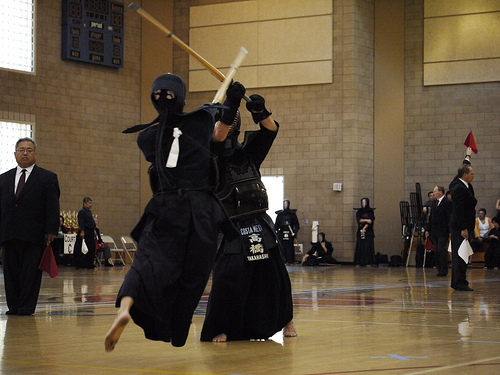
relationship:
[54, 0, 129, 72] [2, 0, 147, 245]
scoreboard on wall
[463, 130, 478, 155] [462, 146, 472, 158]
cloth in hand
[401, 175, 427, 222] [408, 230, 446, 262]
gates near bleachers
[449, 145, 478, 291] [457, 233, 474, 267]
man holding cloth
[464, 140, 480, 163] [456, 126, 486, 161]
hand holding cloth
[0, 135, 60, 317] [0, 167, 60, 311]
man wearing suit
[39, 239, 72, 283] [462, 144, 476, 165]
cloth in hand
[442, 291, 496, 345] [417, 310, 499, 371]
reflection on floor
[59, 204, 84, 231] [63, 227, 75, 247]
trophies on table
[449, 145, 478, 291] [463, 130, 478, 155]
man holding cloth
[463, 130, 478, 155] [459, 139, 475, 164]
cloth on hand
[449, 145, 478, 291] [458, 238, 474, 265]
man holding cloth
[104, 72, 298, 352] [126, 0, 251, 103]
fighters holding bats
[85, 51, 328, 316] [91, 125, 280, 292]
fighters wear robes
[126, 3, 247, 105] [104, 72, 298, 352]
bats used for fighters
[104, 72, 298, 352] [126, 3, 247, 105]
fighters of bats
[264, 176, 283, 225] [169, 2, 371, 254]
door on wall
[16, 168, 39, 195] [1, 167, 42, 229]
tie on man's chest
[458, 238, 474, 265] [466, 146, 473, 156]
cloth in hand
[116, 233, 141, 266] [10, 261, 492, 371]
chair on floor